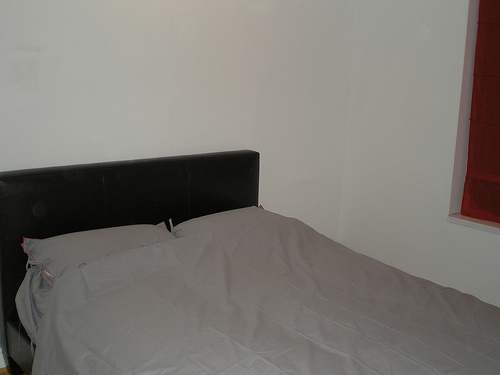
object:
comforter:
[5, 203, 499, 372]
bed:
[0, 148, 499, 372]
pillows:
[23, 220, 209, 295]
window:
[445, 2, 499, 223]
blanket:
[0, 203, 499, 373]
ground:
[321, 125, 367, 162]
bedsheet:
[33, 213, 499, 373]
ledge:
[440, 198, 492, 225]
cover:
[30, 213, 499, 373]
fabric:
[29, 240, 494, 373]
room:
[1, 0, 498, 365]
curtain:
[460, 3, 500, 221]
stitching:
[15, 236, 51, 288]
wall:
[4, 5, 497, 300]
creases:
[191, 287, 269, 329]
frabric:
[127, 251, 285, 323]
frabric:
[271, 287, 409, 372]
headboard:
[2, 150, 263, 294]